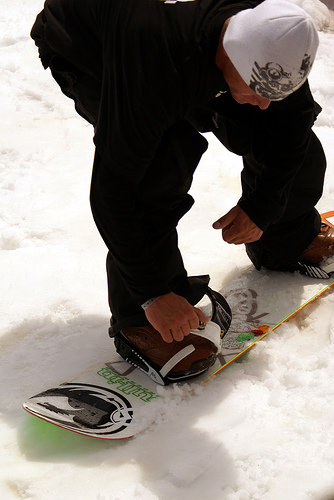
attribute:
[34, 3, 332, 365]
snowboarder — bending over, in black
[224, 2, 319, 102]
cap — white, knit, black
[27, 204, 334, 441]
snowboard — printed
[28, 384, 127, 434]
sticker — circular, black, grey, white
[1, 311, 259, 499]
reflection — green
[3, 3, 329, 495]
snow — on ground, white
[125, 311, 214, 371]
boots — brown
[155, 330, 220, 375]
straps — white, thin, thick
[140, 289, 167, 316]
bracelet — white, gray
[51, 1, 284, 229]
jacket — black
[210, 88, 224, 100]
zipper — silver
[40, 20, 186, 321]
pants — black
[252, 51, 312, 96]
graphics — black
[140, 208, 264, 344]
hands — bare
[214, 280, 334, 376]
edge — orange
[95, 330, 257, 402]
design — green